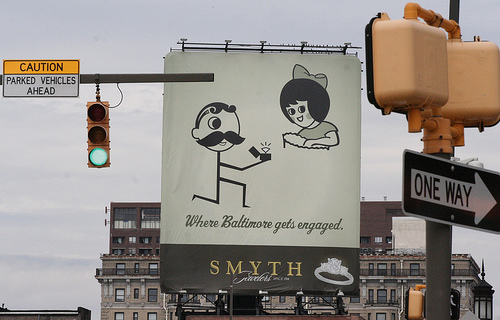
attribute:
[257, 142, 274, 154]
ring — silver, cartoon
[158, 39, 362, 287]
billboard — advertisement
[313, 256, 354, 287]
ring — silver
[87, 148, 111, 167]
light — green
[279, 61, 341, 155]
girl — cartoon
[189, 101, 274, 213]
man — cartoon, kneeling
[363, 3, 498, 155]
object — yellow